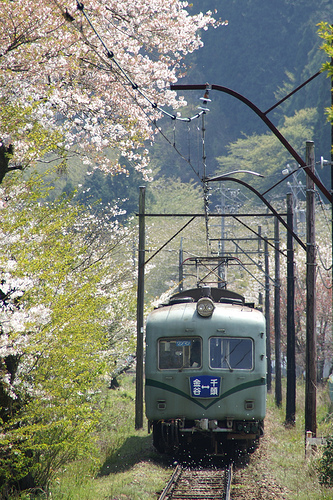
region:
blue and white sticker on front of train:
[189, 376, 218, 395]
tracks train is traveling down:
[150, 440, 240, 499]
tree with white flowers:
[1, 226, 54, 412]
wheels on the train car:
[149, 416, 256, 459]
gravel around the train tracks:
[159, 461, 270, 499]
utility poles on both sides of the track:
[131, 166, 326, 439]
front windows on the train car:
[152, 335, 249, 372]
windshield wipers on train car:
[176, 347, 232, 373]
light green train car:
[146, 297, 268, 429]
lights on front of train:
[154, 400, 253, 412]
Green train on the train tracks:
[145, 299, 268, 464]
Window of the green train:
[154, 334, 256, 371]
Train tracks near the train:
[156, 457, 234, 499]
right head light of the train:
[153, 397, 164, 408]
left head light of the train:
[243, 398, 254, 409]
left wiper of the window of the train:
[217, 351, 236, 370]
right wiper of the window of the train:
[176, 355, 193, 372]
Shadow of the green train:
[94, 433, 171, 478]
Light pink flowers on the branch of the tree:
[1, 0, 229, 182]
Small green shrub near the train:
[311, 434, 331, 491]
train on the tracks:
[134, 272, 286, 472]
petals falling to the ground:
[128, 438, 268, 485]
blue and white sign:
[188, 372, 223, 401]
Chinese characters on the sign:
[191, 378, 201, 396]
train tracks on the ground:
[143, 454, 249, 499]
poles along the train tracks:
[132, 182, 325, 437]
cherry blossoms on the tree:
[0, 1, 224, 187]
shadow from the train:
[92, 432, 162, 478]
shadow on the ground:
[87, 425, 164, 476]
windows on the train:
[153, 328, 253, 380]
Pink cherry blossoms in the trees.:
[2, 2, 154, 142]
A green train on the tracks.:
[125, 293, 295, 455]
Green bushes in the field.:
[27, 218, 116, 495]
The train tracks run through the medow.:
[148, 455, 269, 497]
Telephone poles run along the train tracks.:
[259, 56, 332, 465]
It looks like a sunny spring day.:
[88, 0, 329, 296]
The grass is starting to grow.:
[45, 401, 153, 498]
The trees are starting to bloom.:
[41, 185, 130, 329]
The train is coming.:
[99, 205, 330, 499]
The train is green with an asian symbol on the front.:
[130, 293, 281, 455]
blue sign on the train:
[180, 366, 223, 405]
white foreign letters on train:
[183, 371, 223, 399]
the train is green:
[140, 296, 267, 430]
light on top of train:
[191, 293, 218, 319]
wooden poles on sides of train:
[113, 184, 325, 453]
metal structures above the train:
[155, 192, 290, 305]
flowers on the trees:
[3, 3, 218, 400]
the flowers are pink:
[3, 1, 228, 178]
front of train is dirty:
[141, 318, 266, 426]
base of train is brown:
[153, 417, 277, 461]